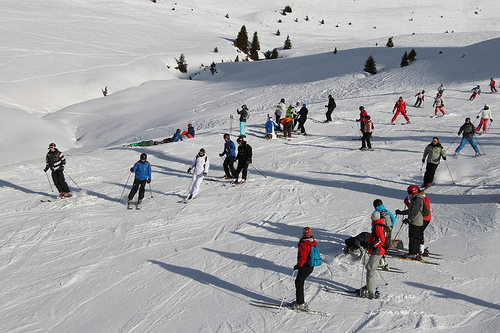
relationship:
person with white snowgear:
[421, 127, 444, 187] [183, 159, 207, 197]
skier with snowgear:
[231, 133, 252, 182] [231, 144, 252, 179]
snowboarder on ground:
[340, 230, 402, 260] [3, 3, 495, 327]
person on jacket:
[121, 140, 153, 218] [129, 158, 158, 183]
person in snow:
[43, 141, 74, 198] [2, 1, 495, 327]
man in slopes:
[128, 153, 151, 204] [118, 49, 485, 294]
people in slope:
[288, 227, 319, 310] [0, 71, 497, 331]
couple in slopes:
[158, 113, 208, 148] [52, 55, 480, 304]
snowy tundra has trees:
[205, 60, 317, 103] [193, 15, 304, 55]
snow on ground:
[0, 210, 279, 333] [8, 212, 438, 331]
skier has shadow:
[287, 219, 329, 314] [139, 254, 294, 314]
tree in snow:
[232, 22, 251, 59] [2, 1, 495, 327]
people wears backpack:
[288, 227, 319, 310] [302, 237, 322, 265]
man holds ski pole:
[119, 149, 156, 204] [119, 168, 134, 197]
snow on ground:
[128, 210, 279, 305] [3, 77, 480, 331]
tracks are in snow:
[146, 283, 213, 319] [29, 197, 214, 332]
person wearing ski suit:
[381, 90, 416, 129] [386, 94, 413, 126]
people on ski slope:
[295, 184, 438, 294] [153, 156, 496, 329]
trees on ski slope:
[211, 17, 305, 72] [4, 2, 498, 330]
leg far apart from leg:
[454, 135, 469, 150] [466, 137, 481, 154]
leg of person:
[454, 135, 469, 150] [453, 116, 482, 156]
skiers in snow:
[28, 73, 498, 305] [2, 1, 495, 327]